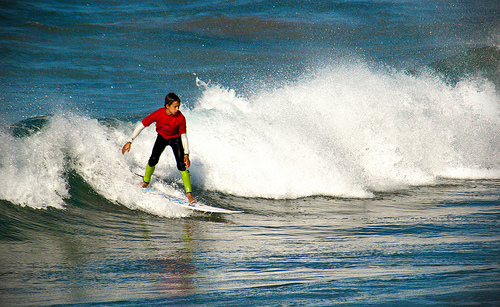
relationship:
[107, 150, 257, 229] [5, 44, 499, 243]
surfboard on wave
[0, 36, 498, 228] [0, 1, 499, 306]
wave in blue water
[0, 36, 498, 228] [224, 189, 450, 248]
wave in blue water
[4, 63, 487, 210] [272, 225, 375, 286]
wave in water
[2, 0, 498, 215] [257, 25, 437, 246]
white cap on wave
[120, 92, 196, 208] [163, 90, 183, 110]
boy has hair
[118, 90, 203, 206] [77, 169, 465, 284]
boy surfing in ocean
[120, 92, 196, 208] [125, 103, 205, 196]
boy wearing suit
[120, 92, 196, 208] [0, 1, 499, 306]
boy in blue water